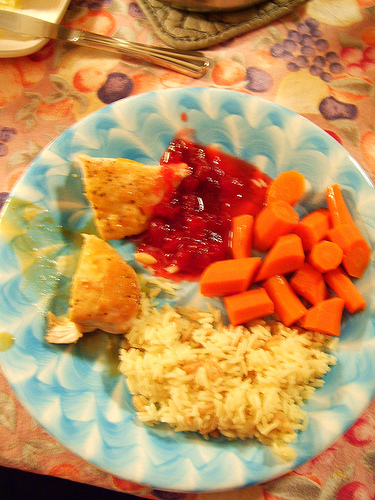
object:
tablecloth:
[1, 1, 373, 498]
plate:
[0, 86, 374, 492]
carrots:
[299, 298, 345, 337]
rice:
[116, 294, 340, 443]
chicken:
[65, 233, 144, 345]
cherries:
[186, 176, 218, 248]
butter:
[1, 0, 30, 18]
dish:
[0, 0, 71, 60]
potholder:
[132, 0, 306, 52]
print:
[0, 3, 375, 193]